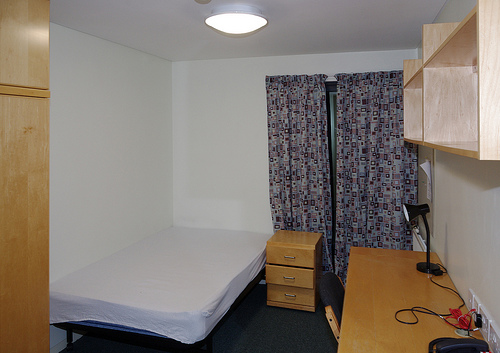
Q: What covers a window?
A: Curtains.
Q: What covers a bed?
A: White sheet.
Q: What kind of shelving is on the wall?
A: Wooden shelving.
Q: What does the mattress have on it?
A: A white sheet.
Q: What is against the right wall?
A: A desk.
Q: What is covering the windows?
A: Long curtains.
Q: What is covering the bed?
A: A white bed sheet.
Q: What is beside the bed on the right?
A: A night stand.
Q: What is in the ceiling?
A: An overhead light.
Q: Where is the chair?
A: Facing the desk.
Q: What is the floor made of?
A: Dark colored carpet.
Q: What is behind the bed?
A: A white wall.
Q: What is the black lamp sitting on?
A: Table.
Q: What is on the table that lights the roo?
A: Lamp.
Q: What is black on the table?
A: Lamp.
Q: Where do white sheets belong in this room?
A: Bed.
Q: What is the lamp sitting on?
A: Long brown table.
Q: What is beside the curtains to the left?
A: White wall.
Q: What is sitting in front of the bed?
A: Brown cabinet.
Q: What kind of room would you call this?
A: Dorm room.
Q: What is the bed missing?
A: Sheets.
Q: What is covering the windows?
A: Curtains.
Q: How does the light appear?
A: Illuminated.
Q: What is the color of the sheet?
A: White.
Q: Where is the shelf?
A: On the wall.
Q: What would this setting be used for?
A: A dorm room.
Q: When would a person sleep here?
A: At night.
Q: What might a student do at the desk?
A: Study.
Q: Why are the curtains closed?
A: For privacy.